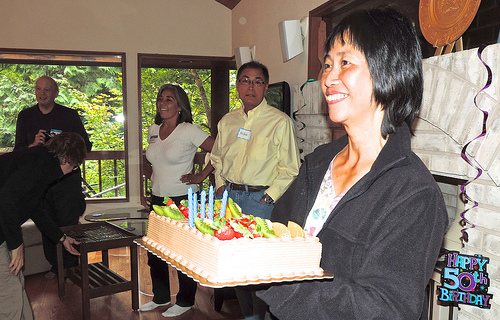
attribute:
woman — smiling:
[249, 1, 460, 316]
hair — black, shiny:
[321, 12, 431, 135]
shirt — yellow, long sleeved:
[210, 96, 305, 198]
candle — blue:
[220, 190, 228, 219]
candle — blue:
[191, 187, 201, 223]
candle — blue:
[208, 179, 217, 223]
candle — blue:
[183, 182, 195, 224]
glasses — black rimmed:
[240, 71, 275, 96]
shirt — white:
[147, 120, 210, 203]